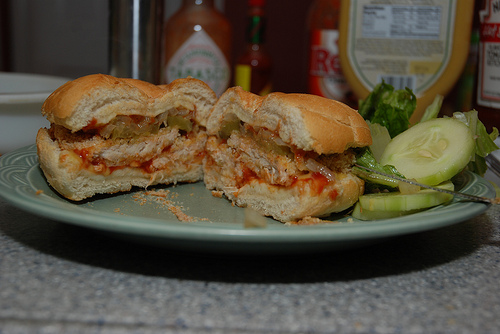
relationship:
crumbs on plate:
[166, 196, 191, 227] [193, 187, 252, 229]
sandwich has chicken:
[41, 70, 371, 236] [207, 120, 317, 190]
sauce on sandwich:
[221, 129, 343, 204] [41, 70, 371, 236]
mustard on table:
[335, 6, 482, 124] [5, 99, 497, 322]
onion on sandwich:
[301, 153, 335, 184] [200, 87, 370, 221]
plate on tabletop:
[0, 144, 495, 261] [1, 195, 496, 332]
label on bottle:
[342, 3, 459, 99] [321, 2, 487, 121]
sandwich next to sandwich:
[35, 71, 213, 200] [200, 87, 370, 221]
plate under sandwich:
[0, 144, 495, 261] [36, 73, 216, 201]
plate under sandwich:
[0, 144, 495, 261] [200, 87, 370, 221]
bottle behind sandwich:
[157, 4, 247, 106] [33, 69, 383, 226]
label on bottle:
[162, 30, 229, 92] [163, 2, 233, 91]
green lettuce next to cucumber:
[362, 75, 417, 126] [380, 118, 473, 185]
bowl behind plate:
[1, 64, 72, 153] [0, 144, 495, 261]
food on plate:
[50, 70, 357, 218] [2, 112, 495, 239]